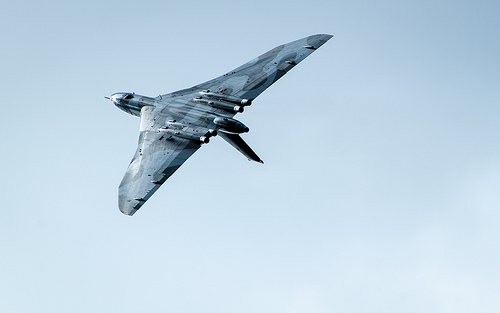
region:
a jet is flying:
[96, 39, 375, 305]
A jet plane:
[93, 43, 238, 248]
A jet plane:
[117, 100, 279, 300]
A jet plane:
[168, 33, 297, 233]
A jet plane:
[53, 8, 295, 309]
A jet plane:
[136, 78, 258, 230]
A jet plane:
[200, 85, 325, 275]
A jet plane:
[168, 134, 219, 196]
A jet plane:
[160, 30, 255, 190]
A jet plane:
[80, 98, 338, 210]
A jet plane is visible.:
[160, 105, 200, 152]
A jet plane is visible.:
[118, 51, 203, 162]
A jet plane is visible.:
[170, 98, 250, 218]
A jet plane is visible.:
[155, 61, 203, 181]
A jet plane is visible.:
[125, 77, 209, 212]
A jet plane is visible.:
[108, 91, 278, 303]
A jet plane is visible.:
[198, 122, 290, 260]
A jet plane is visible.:
[118, 4, 293, 232]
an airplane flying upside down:
[51, 24, 445, 276]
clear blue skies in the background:
[307, 131, 436, 267]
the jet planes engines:
[167, 91, 253, 158]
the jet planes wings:
[74, 111, 225, 247]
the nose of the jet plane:
[79, 79, 158, 124]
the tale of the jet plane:
[206, 119, 317, 214]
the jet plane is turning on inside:
[70, 17, 367, 222]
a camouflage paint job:
[91, 128, 208, 245]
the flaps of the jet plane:
[104, 144, 227, 229]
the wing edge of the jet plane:
[133, 27, 308, 102]